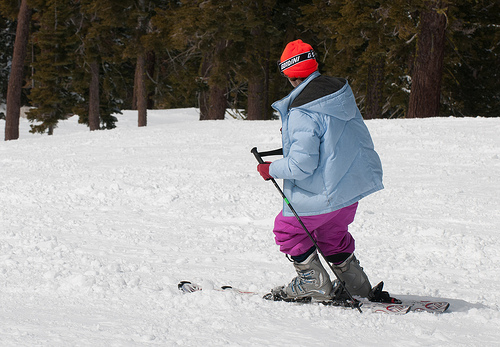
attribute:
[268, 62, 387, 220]
jacket — blue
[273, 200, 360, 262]
sweats — purple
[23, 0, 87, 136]
tree — green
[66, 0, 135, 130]
tree — green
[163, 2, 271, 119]
tree — green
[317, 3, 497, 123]
tree — green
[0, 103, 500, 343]
snow — white, deep, rough, bright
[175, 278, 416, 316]
ski — pink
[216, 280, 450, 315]
ski — pink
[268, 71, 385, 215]
jacket — puffy, light blue, blue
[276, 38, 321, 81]
beanie — neon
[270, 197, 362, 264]
pants — magenta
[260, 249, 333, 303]
boot — silver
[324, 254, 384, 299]
boot — silver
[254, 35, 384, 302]
woman — powder blue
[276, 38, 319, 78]
ski hat — red and black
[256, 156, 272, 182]
glove — red, cold weather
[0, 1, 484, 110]
pine trees — green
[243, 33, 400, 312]
person — skiing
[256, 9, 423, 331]
clothes — snow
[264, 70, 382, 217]
ski jacket — powder blue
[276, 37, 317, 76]
ski cap — orange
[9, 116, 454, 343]
snow — white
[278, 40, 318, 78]
hat — red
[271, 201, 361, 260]
pants — purple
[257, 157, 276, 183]
glove — red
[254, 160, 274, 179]
gloves — red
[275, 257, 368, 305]
snow boots — grey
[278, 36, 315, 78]
cap — red, black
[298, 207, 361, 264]
pants — purple, ski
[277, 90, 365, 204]
jacket — blue, winter, puffy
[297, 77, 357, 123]
hoodie — coat, black and blue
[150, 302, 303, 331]
snow — choppy, winter, thick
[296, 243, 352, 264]
socks — black, pair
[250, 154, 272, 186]
glove — black and red